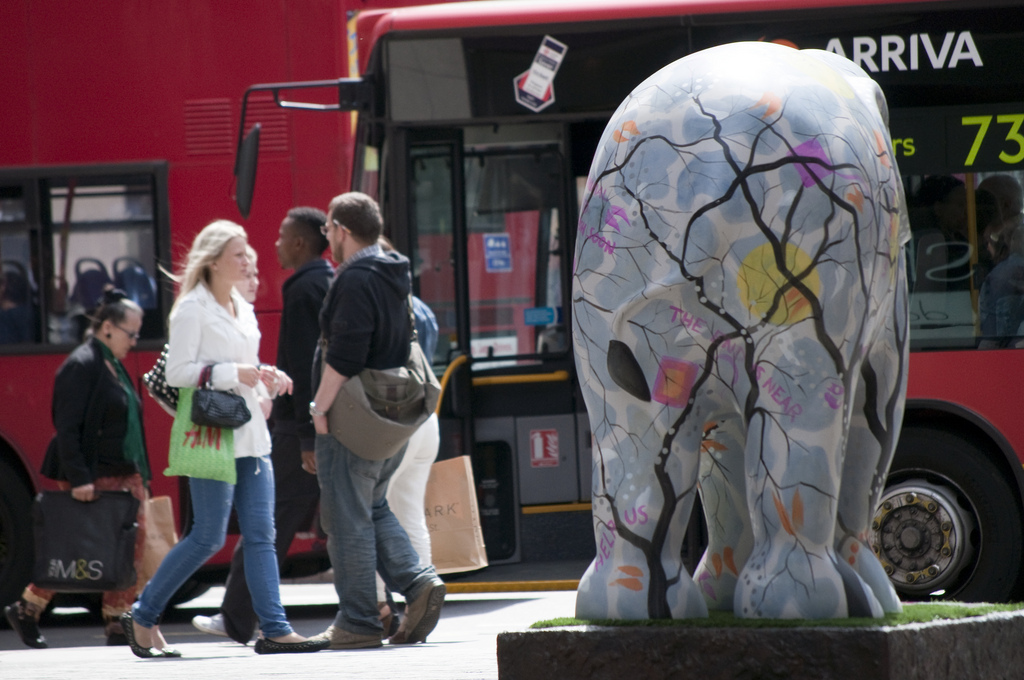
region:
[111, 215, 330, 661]
blond woman walking down a city sidewalk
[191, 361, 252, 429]
blond womans small black purse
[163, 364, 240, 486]
blond womans green shopping bag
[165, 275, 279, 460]
white long sleeved shirt blond woman is wearing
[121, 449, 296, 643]
blue jeans blond woman is wearing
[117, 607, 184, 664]
right black flat the woman is wearing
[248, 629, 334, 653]
left black flat blond woman is wearing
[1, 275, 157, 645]
older, heavy woman with hair in bun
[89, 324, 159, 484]
green scarf of older woman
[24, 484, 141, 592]
black shopping bag of older woman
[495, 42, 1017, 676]
sculpture on square base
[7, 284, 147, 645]
walking woman with bag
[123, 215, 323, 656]
walking woman in blue jeans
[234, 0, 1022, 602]
side of city bus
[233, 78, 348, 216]
mirror on vertical pole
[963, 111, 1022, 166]
green numbers on black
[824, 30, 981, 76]
white word on black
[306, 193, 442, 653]
man with open bag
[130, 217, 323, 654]
person is walking outside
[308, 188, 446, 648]
person is walking outside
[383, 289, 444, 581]
person is walking outside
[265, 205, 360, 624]
person is walking outside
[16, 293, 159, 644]
person is walking outside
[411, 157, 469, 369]
bus has a window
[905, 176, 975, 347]
bus has a window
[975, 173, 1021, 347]
bus has a window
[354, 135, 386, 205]
bus has a window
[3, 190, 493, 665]
People walking on the sidewalk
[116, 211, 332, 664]
Woman in tight blue jeans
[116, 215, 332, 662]
Woman wearing white coat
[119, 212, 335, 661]
Woman in blue jeans has blonde hair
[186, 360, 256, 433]
Small black purse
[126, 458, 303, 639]
Pair of tight blue jeans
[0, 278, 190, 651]
Older woman carrying paper bags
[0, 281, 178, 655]
Older woman wearing black blazer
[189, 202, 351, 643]
Black guy in black coat walking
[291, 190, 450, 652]
Guy wearing eyeglasses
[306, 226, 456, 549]
a person standing outside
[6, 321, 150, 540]
a person standing outside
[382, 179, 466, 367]
a window on the bus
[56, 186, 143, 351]
a window on the bus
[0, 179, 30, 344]
a window on the bus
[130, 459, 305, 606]
jeans are blue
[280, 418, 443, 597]
pants are blue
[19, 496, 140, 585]
bag is black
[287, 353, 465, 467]
a brown bag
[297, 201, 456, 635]
A person is standing up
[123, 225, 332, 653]
A person is standing up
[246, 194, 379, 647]
A person is standing up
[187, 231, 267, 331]
A person is standing up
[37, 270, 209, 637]
A person is standing up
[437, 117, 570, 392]
A window on a vehicle.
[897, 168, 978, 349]
A window on a vehicle.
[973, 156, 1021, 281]
A window on a vehicle.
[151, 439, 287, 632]
a pair of blue jeans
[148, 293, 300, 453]
a white coat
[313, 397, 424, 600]
pants are grey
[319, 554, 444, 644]
some brown shoes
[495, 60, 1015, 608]
statue of an elephant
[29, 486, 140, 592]
a black bag